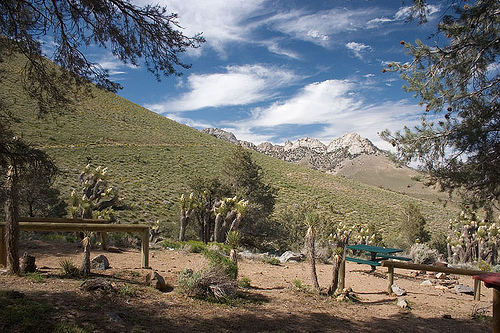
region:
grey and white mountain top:
[256, 132, 383, 167]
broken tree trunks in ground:
[303, 227, 350, 293]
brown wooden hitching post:
[21, 220, 151, 272]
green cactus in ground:
[68, 164, 118, 210]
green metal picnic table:
[347, 242, 412, 273]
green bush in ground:
[180, 245, 249, 303]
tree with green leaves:
[378, 2, 498, 226]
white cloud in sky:
[251, 77, 361, 127]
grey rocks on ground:
[391, 282, 408, 310]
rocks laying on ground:
[419, 268, 471, 296]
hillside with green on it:
[2, 38, 497, 263]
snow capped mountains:
[205, 129, 412, 180]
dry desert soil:
[2, 234, 498, 331]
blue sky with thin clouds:
[13, 36, 498, 183]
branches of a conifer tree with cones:
[367, 43, 499, 221]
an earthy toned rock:
[115, 267, 168, 293]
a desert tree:
[0, 131, 53, 279]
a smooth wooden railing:
[5, 219, 157, 274]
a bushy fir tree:
[193, 141, 280, 228]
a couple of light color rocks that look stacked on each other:
[387, 281, 414, 310]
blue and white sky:
[205, 17, 370, 145]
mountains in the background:
[265, 128, 386, 172]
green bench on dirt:
[338, 233, 413, 284]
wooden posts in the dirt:
[19, 212, 166, 274]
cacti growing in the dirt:
[298, 207, 353, 307]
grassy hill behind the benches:
[48, 99, 199, 204]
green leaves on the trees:
[396, 58, 484, 168]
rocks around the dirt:
[226, 240, 313, 272]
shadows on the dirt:
[55, 288, 283, 328]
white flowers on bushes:
[434, 213, 497, 247]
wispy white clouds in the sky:
[202, 13, 323, 121]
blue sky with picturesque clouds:
[247, 30, 392, 138]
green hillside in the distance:
[235, 160, 355, 234]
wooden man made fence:
[15, 203, 166, 278]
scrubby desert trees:
[154, 161, 248, 262]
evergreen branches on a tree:
[398, 40, 498, 170]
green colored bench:
[341, 218, 402, 286]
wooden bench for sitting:
[378, 250, 498, 317]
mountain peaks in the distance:
[232, 94, 380, 185]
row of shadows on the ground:
[181, 243, 438, 331]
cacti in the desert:
[172, 193, 257, 249]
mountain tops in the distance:
[288, 133, 380, 175]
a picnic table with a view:
[345, 233, 408, 276]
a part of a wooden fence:
[380, 253, 490, 297]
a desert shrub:
[169, 243, 245, 297]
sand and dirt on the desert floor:
[257, 295, 337, 331]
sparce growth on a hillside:
[88, 103, 201, 183]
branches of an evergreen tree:
[408, 15, 498, 200]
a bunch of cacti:
[439, 219, 499, 260]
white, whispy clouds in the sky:
[205, 45, 371, 122]